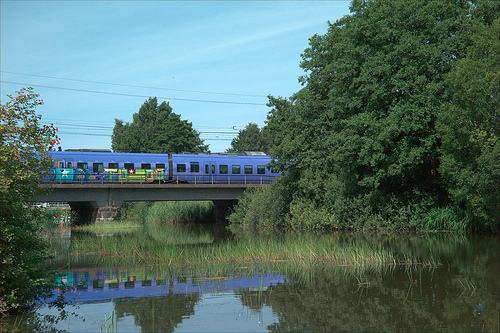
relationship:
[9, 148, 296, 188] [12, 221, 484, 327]
train over water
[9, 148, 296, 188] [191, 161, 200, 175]
train has window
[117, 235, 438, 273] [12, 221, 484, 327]
grass in water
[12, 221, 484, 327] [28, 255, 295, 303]
water has reflection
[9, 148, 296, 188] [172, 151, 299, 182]
train has train car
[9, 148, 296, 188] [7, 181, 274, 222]
train on bridge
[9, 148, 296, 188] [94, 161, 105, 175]
train has window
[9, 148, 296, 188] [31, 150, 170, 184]
train has train car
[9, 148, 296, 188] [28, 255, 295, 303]
train has reflection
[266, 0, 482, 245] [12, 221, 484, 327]
tree next to water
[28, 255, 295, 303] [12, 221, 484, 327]
reflection in water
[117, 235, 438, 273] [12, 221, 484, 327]
grass growing out water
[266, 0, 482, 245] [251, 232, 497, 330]
tree has reflection